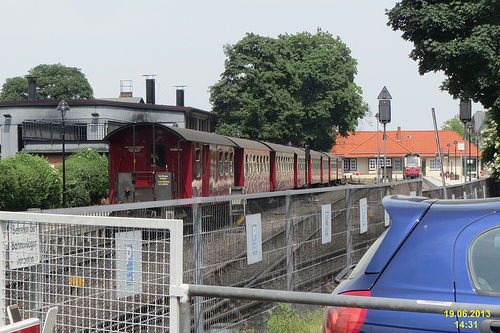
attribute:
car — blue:
[318, 193, 498, 332]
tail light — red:
[322, 291, 369, 330]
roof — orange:
[331, 131, 482, 156]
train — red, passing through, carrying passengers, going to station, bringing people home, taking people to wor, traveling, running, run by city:
[105, 124, 345, 199]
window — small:
[222, 150, 236, 174]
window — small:
[259, 155, 266, 172]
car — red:
[231, 136, 274, 196]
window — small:
[280, 160, 287, 168]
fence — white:
[0, 210, 186, 333]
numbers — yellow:
[444, 308, 493, 330]